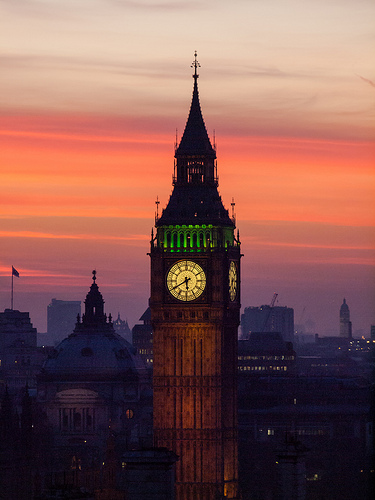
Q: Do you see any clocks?
A: Yes, there is a clock.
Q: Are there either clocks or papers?
A: Yes, there is a clock.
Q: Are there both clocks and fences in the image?
A: No, there is a clock but no fences.